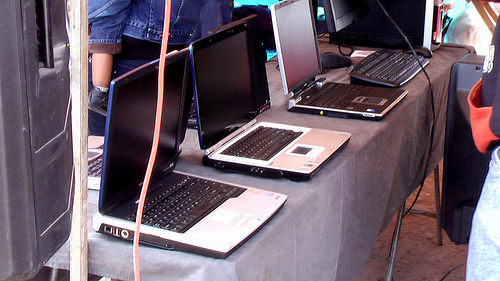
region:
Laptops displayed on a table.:
[98, 4, 453, 268]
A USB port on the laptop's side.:
[96, 216, 125, 242]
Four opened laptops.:
[93, 4, 450, 261]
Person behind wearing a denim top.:
[86, 2, 226, 74]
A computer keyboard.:
[348, 37, 438, 91]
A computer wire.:
[374, 3, 443, 242]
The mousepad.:
[281, 136, 326, 166]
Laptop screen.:
[186, 16, 275, 142]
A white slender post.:
[61, 1, 96, 276]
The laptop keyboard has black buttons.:
[118, 166, 256, 232]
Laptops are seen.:
[93, 10, 440, 257]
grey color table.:
[86, 220, 296, 275]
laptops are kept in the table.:
[100, 55, 337, 266]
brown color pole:
[61, 21, 116, 268]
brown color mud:
[409, 234, 439, 277]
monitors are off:
[102, 50, 304, 195]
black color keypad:
[146, 183, 207, 223]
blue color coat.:
[96, 13, 161, 37]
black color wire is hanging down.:
[401, 28, 458, 183]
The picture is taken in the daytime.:
[13, 40, 495, 250]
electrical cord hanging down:
[125, 0, 175, 273]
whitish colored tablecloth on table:
[300, 175, 365, 270]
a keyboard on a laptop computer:
[226, 120, 301, 170]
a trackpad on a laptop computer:
[285, 137, 311, 157]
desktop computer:
[326, 0, 442, 85]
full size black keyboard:
[346, 40, 431, 85]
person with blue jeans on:
[470, 17, 491, 268]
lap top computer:
[90, 65, 293, 266]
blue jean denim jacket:
[133, 0, 200, 44]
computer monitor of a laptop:
[198, 46, 290, 131]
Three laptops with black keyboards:
[94, 0, 405, 261]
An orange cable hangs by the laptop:
[111, 0, 186, 276]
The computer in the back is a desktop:
[322, 0, 444, 86]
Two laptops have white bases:
[87, 12, 350, 262]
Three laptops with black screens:
[97, 2, 407, 262]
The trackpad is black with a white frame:
[279, 140, 330, 160]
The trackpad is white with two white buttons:
[207, 206, 253, 229]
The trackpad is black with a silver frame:
[348, 91, 391, 106]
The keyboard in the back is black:
[351, 45, 433, 85]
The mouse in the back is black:
[404, 45, 434, 57]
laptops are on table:
[90, 75, 396, 200]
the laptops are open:
[87, 59, 386, 197]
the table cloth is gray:
[292, 205, 384, 268]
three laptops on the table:
[108, 13, 493, 146]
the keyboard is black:
[351, 33, 421, 101]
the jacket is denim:
[133, 7, 220, 44]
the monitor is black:
[107, 43, 187, 195]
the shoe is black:
[82, 73, 112, 123]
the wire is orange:
[152, 0, 187, 247]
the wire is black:
[392, 21, 437, 124]